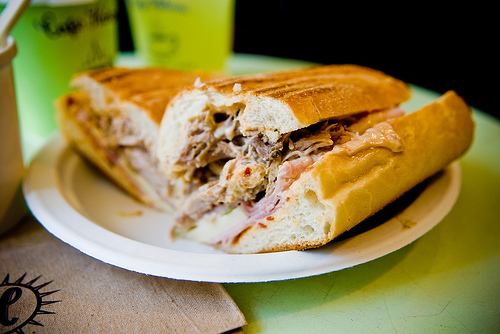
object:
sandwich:
[153, 65, 473, 255]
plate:
[23, 133, 465, 285]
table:
[3, 52, 499, 333]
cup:
[1, 0, 119, 137]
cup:
[128, 0, 233, 72]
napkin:
[0, 232, 247, 333]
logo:
[0, 273, 63, 332]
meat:
[173, 110, 403, 244]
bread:
[153, 64, 476, 255]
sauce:
[223, 185, 288, 245]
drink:
[9, 5, 113, 72]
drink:
[125, 0, 235, 77]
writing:
[32, 3, 117, 40]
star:
[0, 269, 64, 333]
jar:
[0, 28, 28, 243]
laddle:
[0, 1, 35, 45]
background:
[0, 0, 498, 122]